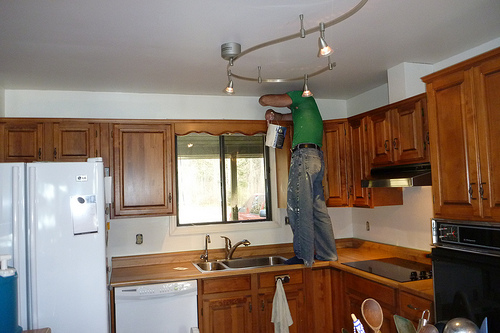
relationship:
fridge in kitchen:
[2, 138, 132, 331] [7, 90, 452, 303]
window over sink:
[169, 127, 285, 223] [181, 237, 291, 283]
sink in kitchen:
[181, 237, 291, 283] [13, 55, 498, 325]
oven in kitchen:
[428, 215, 498, 328] [13, 55, 498, 325]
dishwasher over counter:
[61, 234, 245, 331] [99, 230, 460, 316]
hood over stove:
[360, 167, 432, 190] [340, 254, 430, 284]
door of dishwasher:
[114, 285, 200, 331] [110, 273, 203, 327]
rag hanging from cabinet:
[271, 278, 293, 331] [192, 262, 323, 330]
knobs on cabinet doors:
[466, 180, 486, 198] [419, 39, 498, 224]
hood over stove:
[360, 167, 432, 190] [430, 217, 498, 331]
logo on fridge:
[75, 173, 87, 180] [2, 160, 107, 331]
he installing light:
[286, 80, 342, 272] [315, 34, 333, 63]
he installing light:
[286, 80, 342, 272] [223, 73, 235, 97]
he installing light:
[286, 80, 342, 272] [299, 73, 313, 98]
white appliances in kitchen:
[27, 156, 202, 321] [1, 0, 498, 332]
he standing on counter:
[286, 80, 342, 272] [109, 237, 434, 299]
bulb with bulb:
[299, 90, 314, 98] [299, 90, 314, 98]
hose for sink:
[197, 232, 221, 270] [189, 248, 308, 275]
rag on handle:
[271, 278, 293, 331] [269, 271, 289, 283]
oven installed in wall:
[428, 215, 500, 329] [346, 32, 496, 330]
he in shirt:
[286, 80, 342, 272] [286, 88, 324, 147]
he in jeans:
[286, 80, 342, 272] [286, 144, 338, 264]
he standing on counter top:
[286, 80, 342, 272] [108, 236, 436, 300]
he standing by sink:
[286, 80, 342, 272] [190, 252, 290, 274]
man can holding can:
[256, 90, 339, 264] [264, 120, 285, 150]